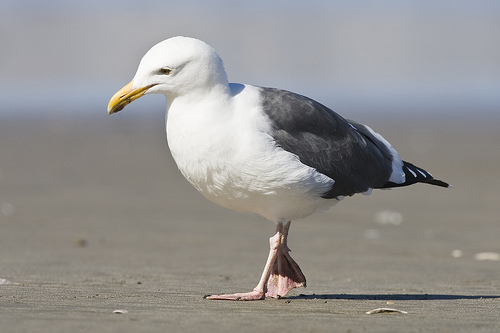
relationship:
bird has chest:
[107, 36, 454, 302] [164, 102, 236, 192]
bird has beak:
[107, 36, 454, 302] [107, 79, 150, 115]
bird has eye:
[107, 36, 454, 302] [158, 68, 173, 76]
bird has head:
[107, 36, 454, 302] [106, 35, 232, 116]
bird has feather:
[107, 36, 454, 302] [277, 128, 320, 153]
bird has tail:
[107, 36, 454, 302] [418, 166, 455, 189]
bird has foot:
[107, 36, 454, 302] [203, 290, 267, 302]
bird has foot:
[107, 36, 454, 302] [267, 246, 307, 300]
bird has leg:
[107, 36, 454, 302] [255, 220, 282, 291]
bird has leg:
[107, 36, 454, 302] [282, 220, 290, 252]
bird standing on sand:
[107, 36, 454, 302] [1, 113, 498, 332]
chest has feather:
[164, 102, 236, 192] [166, 110, 182, 146]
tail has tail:
[395, 158, 454, 189] [418, 166, 455, 189]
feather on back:
[264, 87, 292, 98] [230, 81, 399, 155]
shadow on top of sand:
[280, 292, 499, 300] [1, 113, 498, 332]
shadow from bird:
[280, 292, 499, 300] [107, 36, 454, 302]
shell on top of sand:
[364, 308, 406, 314] [1, 113, 498, 332]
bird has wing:
[107, 36, 454, 302] [261, 86, 366, 149]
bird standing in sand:
[107, 36, 454, 302] [1, 113, 498, 332]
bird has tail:
[107, 36, 454, 302] [395, 158, 454, 189]